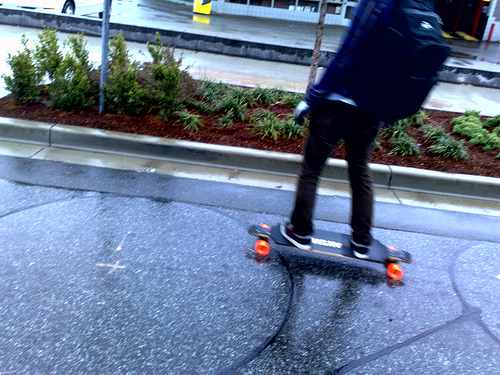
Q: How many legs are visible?
A: 2.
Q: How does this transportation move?
A: Wheels.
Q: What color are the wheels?
A: Orange.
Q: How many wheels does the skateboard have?
A: 4.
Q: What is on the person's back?
A: Backpack.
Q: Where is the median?
A: In front of the person.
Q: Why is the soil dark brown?
A: Mulch.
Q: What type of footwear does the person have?
A: Tennis shoes.